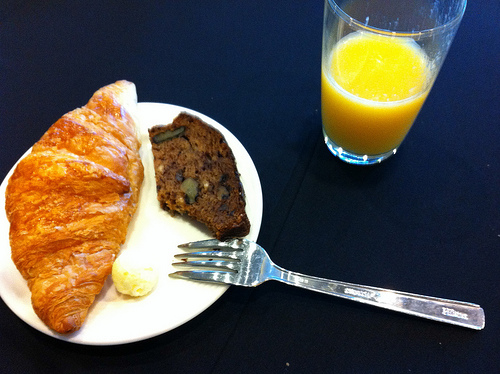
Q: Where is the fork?
A: On the side of the plate.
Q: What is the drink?
A: Juice.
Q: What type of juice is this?
A: Orange.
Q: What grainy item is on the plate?
A: A croissant.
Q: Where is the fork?
A: On the plate.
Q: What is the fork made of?
A: Metal.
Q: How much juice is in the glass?
A: Half a glass.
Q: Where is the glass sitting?
A: On a blue table.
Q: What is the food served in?
A: White plate.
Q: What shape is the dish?
A: Round.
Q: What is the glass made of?
A: Glass.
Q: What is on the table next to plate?
A: Orange juice in a glass.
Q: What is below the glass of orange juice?
A: Silver fork on table.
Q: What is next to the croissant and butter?
A: Piece of meat on plate.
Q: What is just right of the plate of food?
A: Clear glass with orange juice.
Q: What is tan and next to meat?
A: Large flaky croissant on plate.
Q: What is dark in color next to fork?
A: Brown meat on plate.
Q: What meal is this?
A: Breakfast.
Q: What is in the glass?
A: Orange juice.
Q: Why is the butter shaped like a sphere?
A: To amuse the diner.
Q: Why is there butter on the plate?
A: To spread on the croissant.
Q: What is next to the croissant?
A: A slice of banana bread.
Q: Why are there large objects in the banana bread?
A: Walnuts are part of the recipe.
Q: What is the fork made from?
A: Stainless steel.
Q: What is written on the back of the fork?
A: The name of the manufacturer.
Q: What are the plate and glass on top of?
A: A table.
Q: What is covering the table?
A: A blue tablecloth.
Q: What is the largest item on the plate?
A: Croissant.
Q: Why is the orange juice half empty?
A: Half has been consumed.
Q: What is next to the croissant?
A: A slice of bread.